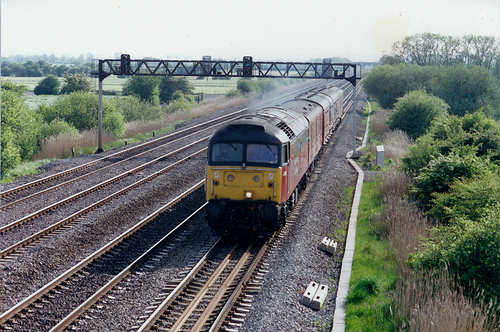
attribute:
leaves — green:
[397, 96, 437, 136]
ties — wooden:
[298, 275, 328, 315]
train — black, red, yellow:
[201, 84, 347, 236]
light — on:
[238, 189, 255, 204]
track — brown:
[6, 181, 209, 330]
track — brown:
[132, 233, 274, 330]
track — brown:
[3, 137, 209, 257]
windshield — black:
[207, 138, 282, 168]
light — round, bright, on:
[244, 186, 256, 202]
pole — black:
[89, 54, 359, 84]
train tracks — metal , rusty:
[5, 89, 301, 330]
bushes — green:
[360, 55, 481, 295]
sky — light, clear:
[1, 1, 482, 66]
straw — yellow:
[379, 118, 479, 330]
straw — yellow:
[41, 131, 104, 152]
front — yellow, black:
[202, 122, 287, 232]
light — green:
[235, 51, 260, 85]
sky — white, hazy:
[2, 2, 498, 60]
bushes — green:
[362, 51, 498, 331]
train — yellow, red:
[192, 76, 361, 237]